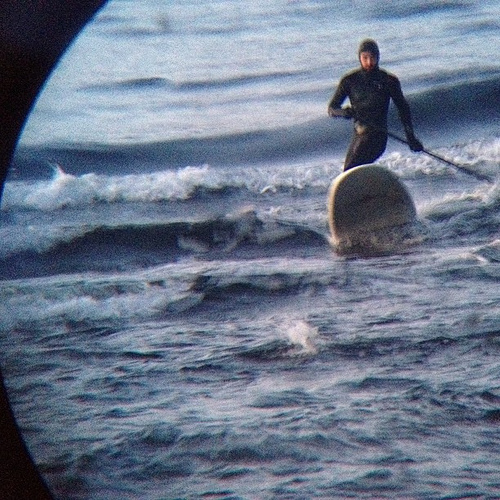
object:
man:
[326, 37, 424, 172]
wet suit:
[326, 37, 424, 172]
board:
[326, 161, 420, 244]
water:
[0, 0, 500, 499]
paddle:
[347, 109, 497, 187]